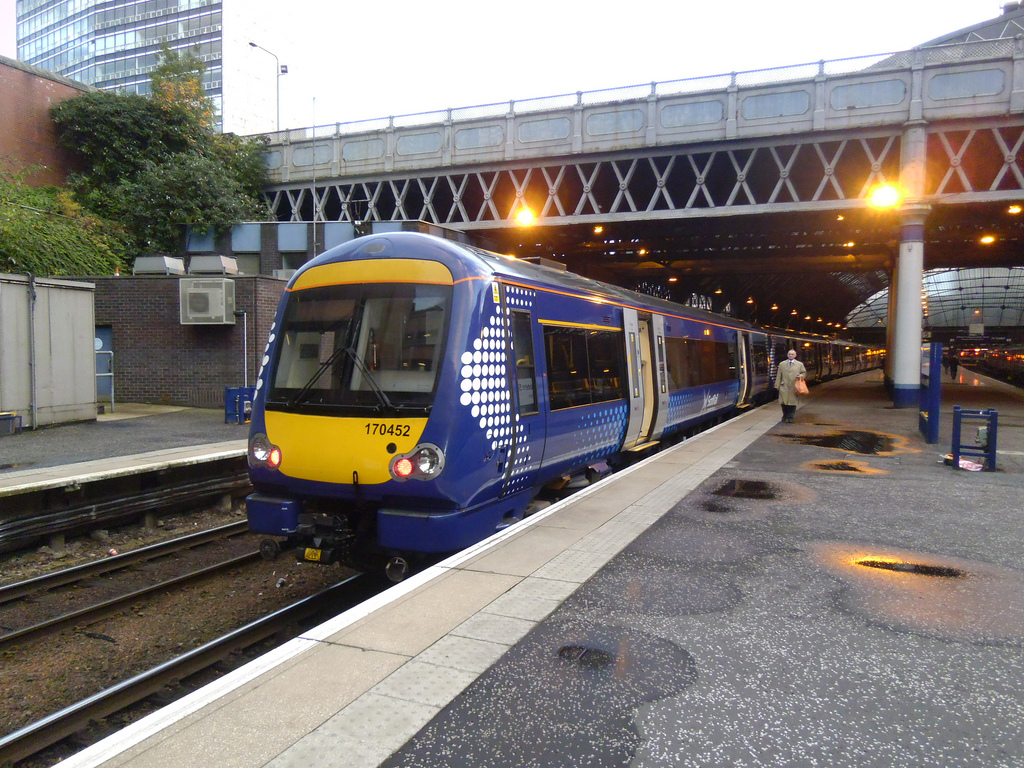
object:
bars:
[937, 406, 997, 474]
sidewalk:
[125, 397, 789, 753]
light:
[841, 156, 934, 214]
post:
[887, 230, 932, 392]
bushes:
[0, 36, 288, 256]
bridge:
[232, 39, 1023, 231]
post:
[889, 113, 933, 404]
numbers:
[365, 419, 415, 441]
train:
[244, 215, 845, 546]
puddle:
[801, 448, 872, 482]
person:
[762, 346, 814, 422]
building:
[0, 0, 224, 120]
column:
[881, 198, 936, 417]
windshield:
[287, 314, 424, 391]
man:
[770, 340, 812, 431]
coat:
[776, 358, 809, 409]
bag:
[793, 379, 811, 396]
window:
[534, 314, 629, 418]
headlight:
[380, 432, 438, 495]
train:
[197, 221, 785, 600]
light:
[487, 184, 571, 236]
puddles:
[849, 541, 976, 587]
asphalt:
[384, 389, 1017, 767]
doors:
[23, 273, 106, 429]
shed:
[9, 210, 133, 468]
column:
[881, 204, 929, 415]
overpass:
[173, 22, 1024, 327]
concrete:
[66, 366, 812, 767]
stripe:
[196, 413, 754, 698]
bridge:
[242, 26, 999, 248]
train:
[225, 216, 872, 569]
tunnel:
[531, 164, 903, 406]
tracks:
[17, 503, 293, 730]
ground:
[0, 497, 346, 757]